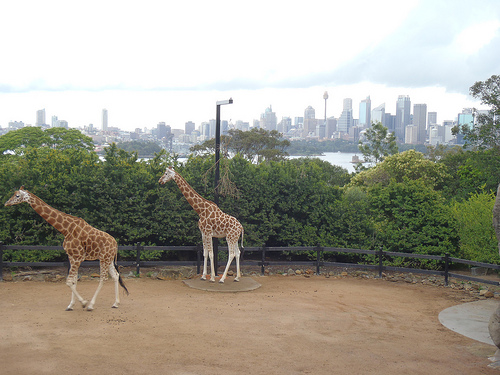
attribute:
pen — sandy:
[5, 245, 497, 373]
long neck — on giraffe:
[154, 107, 264, 342]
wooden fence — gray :
[2, 244, 497, 286]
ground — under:
[395, 132, 435, 150]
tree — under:
[372, 144, 442, 231]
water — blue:
[106, 141, 432, 196]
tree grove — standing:
[2, 122, 498, 257]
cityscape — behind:
[29, 82, 498, 172]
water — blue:
[82, 149, 446, 176]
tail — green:
[239, 222, 245, 257]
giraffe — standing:
[152, 162, 254, 289]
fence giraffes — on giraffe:
[272, 239, 497, 299]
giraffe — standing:
[4, 188, 126, 305]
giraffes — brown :
[96, 139, 266, 274]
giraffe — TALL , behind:
[156, 162, 243, 281]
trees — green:
[263, 162, 465, 239]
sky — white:
[253, 22, 469, 103]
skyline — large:
[15, 72, 498, 152]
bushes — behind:
[5, 143, 477, 207]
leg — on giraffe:
[201, 239, 208, 286]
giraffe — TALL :
[1, 181, 129, 318]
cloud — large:
[219, 19, 477, 100]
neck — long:
[176, 167, 207, 211]